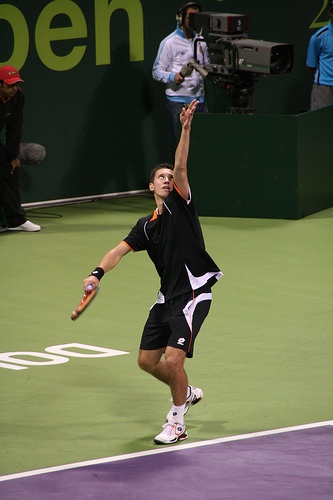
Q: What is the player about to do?
A: Hit the ball.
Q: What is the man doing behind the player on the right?
A: Filming.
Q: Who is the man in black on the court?
A: Player.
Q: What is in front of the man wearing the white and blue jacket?
A: Camera.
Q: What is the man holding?
A: Tennis racket.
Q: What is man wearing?
A: Black shirt.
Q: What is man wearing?
A: Black shorts.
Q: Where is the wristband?
A: On wrist.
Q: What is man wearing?
A: Ear phones.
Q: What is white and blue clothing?
A: Jacket.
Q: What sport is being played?
A: Tennis.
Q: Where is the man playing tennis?
A: At a tennis court.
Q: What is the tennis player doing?
A: Serving.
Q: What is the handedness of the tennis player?
A: Right handed.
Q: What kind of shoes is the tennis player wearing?
A: Tennis shoes.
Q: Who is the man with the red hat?
A: A line judge.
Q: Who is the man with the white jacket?
A: A cameraman.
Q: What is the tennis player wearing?
A: Black shirt and shorts.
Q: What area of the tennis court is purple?
A: The in-bounds area.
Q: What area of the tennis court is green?
A: The out-of-bounds area.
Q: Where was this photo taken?
A: At a tennis match.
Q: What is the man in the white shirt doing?
A: Recording with a camera.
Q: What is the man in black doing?
A: Playing tennis.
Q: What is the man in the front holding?
A: A tennis racket.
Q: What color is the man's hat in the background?
A: Red.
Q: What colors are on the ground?
A: Purple, white, and green.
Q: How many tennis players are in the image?
A: One.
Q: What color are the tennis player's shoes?
A: Black and white.